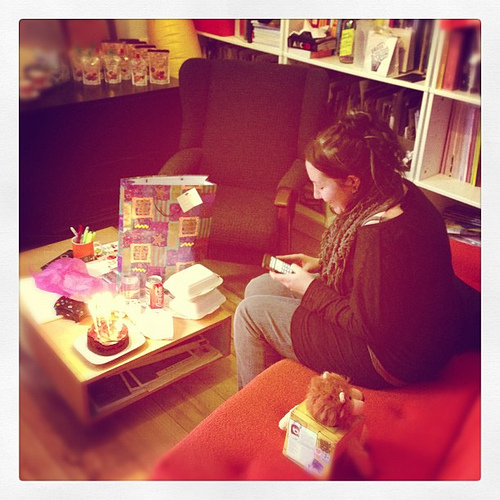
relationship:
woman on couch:
[233, 107, 455, 399] [138, 230, 482, 478]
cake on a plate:
[84, 316, 131, 355] [70, 316, 149, 368]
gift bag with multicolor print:
[120, 170, 219, 295] [132, 194, 205, 260]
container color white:
[167, 261, 224, 301] [190, 271, 195, 281]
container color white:
[165, 289, 229, 320] [190, 271, 195, 281]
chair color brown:
[155, 55, 327, 288] [251, 107, 278, 147]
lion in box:
[275, 369, 384, 484] [286, 399, 364, 478]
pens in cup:
[68, 226, 95, 247] [70, 233, 96, 260]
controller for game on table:
[52, 291, 86, 328] [29, 225, 231, 424]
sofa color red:
[138, 230, 482, 478] [409, 408, 451, 459]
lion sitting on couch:
[275, 369, 384, 484] [138, 230, 482, 478]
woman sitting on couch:
[233, 107, 455, 399] [138, 230, 482, 478]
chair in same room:
[155, 55, 327, 288] [20, 21, 482, 481]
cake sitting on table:
[84, 316, 131, 355] [29, 225, 231, 424]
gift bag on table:
[120, 170, 219, 295] [29, 225, 231, 424]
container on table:
[167, 261, 224, 301] [29, 225, 231, 424]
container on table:
[165, 289, 229, 320] [29, 225, 231, 424]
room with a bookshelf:
[20, 21, 482, 481] [200, 20, 482, 249]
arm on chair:
[270, 154, 316, 255] [155, 55, 327, 288]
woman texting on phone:
[233, 107, 455, 399] [260, 250, 298, 279]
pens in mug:
[68, 226, 95, 247] [70, 233, 96, 260]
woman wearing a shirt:
[233, 107, 455, 399] [290, 180, 461, 392]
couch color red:
[138, 230, 482, 478] [409, 408, 451, 459]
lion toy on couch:
[275, 369, 384, 484] [138, 230, 482, 478]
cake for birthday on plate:
[84, 316, 131, 355] [70, 316, 149, 368]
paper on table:
[35, 256, 101, 297] [29, 225, 231, 424]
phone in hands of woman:
[260, 250, 298, 279] [233, 107, 455, 399]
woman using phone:
[233, 107, 455, 399] [260, 250, 298, 279]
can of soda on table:
[141, 273, 166, 311] [29, 225, 231, 424]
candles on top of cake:
[83, 297, 125, 337] [84, 316, 131, 355]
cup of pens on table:
[70, 233, 96, 260] [29, 225, 231, 424]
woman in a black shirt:
[233, 107, 455, 399] [290, 180, 461, 392]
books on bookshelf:
[440, 102, 484, 185] [200, 20, 482, 249]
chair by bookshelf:
[155, 55, 327, 288] [200, 20, 482, 249]